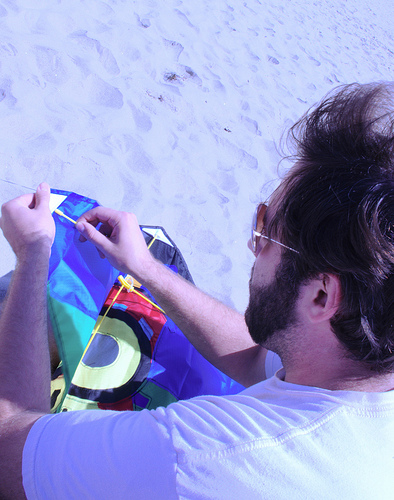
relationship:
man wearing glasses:
[2, 77, 394, 498] [244, 194, 353, 285]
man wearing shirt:
[2, 77, 394, 498] [18, 371, 393, 499]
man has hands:
[2, 77, 394, 498] [0, 183, 171, 288]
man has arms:
[2, 77, 394, 498] [4, 261, 255, 458]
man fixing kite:
[2, 77, 394, 498] [17, 182, 245, 427]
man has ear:
[2, 77, 394, 498] [300, 264, 346, 326]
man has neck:
[2, 77, 394, 498] [267, 334, 392, 394]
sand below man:
[0, 1, 393, 323] [2, 77, 394, 498]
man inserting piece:
[2, 77, 394, 498] [52, 201, 76, 233]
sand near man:
[0, 1, 393, 323] [2, 77, 394, 498]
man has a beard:
[2, 77, 394, 498] [241, 258, 305, 353]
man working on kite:
[2, 77, 394, 498] [17, 182, 245, 427]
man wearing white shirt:
[2, 77, 394, 498] [18, 371, 393, 499]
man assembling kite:
[2, 77, 394, 498] [17, 182, 245, 427]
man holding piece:
[2, 77, 394, 498] [52, 201, 76, 233]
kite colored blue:
[17, 182, 245, 427] [166, 344, 194, 382]